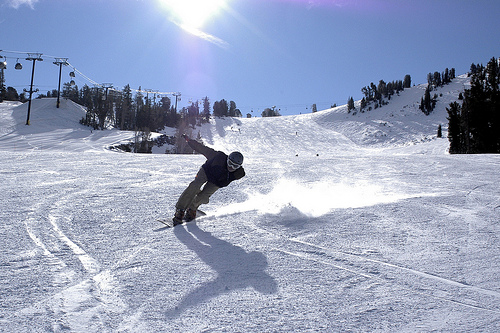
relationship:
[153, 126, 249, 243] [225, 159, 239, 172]
man wearing goggles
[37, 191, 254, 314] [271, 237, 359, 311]
ground with snow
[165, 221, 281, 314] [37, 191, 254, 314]
shadow on ground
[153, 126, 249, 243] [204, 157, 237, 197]
man wearing jacket